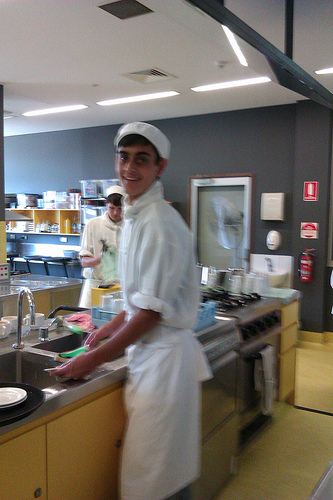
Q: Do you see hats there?
A: Yes, there is a hat.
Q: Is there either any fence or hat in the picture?
A: Yes, there is a hat.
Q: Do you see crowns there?
A: No, there are no crowns.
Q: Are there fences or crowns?
A: No, there are no crowns or fences.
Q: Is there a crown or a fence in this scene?
A: No, there are no crowns or fences.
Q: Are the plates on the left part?
A: Yes, the plates are on the left of the image.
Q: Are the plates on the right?
A: No, the plates are on the left of the image.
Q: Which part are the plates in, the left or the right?
A: The plates are on the left of the image.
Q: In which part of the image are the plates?
A: The plates are on the left of the image.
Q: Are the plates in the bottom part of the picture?
A: Yes, the plates are in the bottom of the image.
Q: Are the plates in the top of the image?
A: No, the plates are in the bottom of the image.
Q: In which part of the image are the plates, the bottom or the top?
A: The plates are in the bottom of the image.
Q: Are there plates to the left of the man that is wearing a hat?
A: Yes, there are plates to the left of the man.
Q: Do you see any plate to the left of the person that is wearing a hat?
A: Yes, there are plates to the left of the man.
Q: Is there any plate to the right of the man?
A: No, the plates are to the left of the man.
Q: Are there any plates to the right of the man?
A: No, the plates are to the left of the man.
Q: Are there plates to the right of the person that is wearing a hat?
A: No, the plates are to the left of the man.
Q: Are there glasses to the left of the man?
A: No, there are plates to the left of the man.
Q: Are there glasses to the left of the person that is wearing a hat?
A: No, there are plates to the left of the man.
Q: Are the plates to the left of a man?
A: Yes, the plates are to the left of a man.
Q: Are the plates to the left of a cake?
A: No, the plates are to the left of a man.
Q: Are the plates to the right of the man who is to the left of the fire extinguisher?
A: No, the plates are to the left of the man.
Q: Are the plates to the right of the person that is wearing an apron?
A: No, the plates are to the left of the man.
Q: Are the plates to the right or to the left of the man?
A: The plates are to the left of the man.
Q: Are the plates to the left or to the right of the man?
A: The plates are to the left of the man.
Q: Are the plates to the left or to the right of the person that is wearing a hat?
A: The plates are to the left of the man.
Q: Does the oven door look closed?
A: Yes, the oven door is closed.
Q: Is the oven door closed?
A: Yes, the oven door is closed.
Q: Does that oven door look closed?
A: Yes, the oven door is closed.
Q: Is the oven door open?
A: No, the oven door is closed.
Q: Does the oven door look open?
A: No, the oven door is closed.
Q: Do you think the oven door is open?
A: No, the oven door is closed.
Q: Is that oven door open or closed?
A: The oven door is closed.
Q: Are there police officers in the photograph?
A: No, there are no police officers.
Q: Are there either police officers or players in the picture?
A: No, there are no police officers or players.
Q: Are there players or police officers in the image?
A: No, there are no police officers or players.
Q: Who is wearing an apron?
A: The man is wearing an apron.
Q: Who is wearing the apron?
A: The man is wearing an apron.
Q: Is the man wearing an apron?
A: Yes, the man is wearing an apron.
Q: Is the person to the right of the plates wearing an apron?
A: Yes, the man is wearing an apron.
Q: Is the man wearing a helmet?
A: No, the man is wearing an apron.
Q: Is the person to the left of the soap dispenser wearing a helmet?
A: No, the man is wearing an apron.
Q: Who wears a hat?
A: The man wears a hat.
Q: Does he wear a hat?
A: Yes, the man wears a hat.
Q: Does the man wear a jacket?
A: No, the man wears a hat.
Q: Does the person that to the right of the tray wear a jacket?
A: No, the man wears a hat.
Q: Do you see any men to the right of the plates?
A: Yes, there is a man to the right of the plates.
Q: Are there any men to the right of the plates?
A: Yes, there is a man to the right of the plates.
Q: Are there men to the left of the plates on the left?
A: No, the man is to the right of the plates.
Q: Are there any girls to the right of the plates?
A: No, there is a man to the right of the plates.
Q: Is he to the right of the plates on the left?
A: Yes, the man is to the right of the plates.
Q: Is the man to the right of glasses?
A: No, the man is to the right of the plates.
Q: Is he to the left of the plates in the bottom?
A: No, the man is to the right of the plates.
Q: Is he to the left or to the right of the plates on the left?
A: The man is to the right of the plates.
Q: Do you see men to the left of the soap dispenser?
A: Yes, there is a man to the left of the soap dispenser.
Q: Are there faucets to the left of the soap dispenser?
A: No, there is a man to the left of the soap dispenser.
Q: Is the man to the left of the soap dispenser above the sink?
A: Yes, the man is to the left of the soap dispenser.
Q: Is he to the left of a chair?
A: No, the man is to the left of the soap dispenser.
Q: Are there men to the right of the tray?
A: Yes, there is a man to the right of the tray.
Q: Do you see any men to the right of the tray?
A: Yes, there is a man to the right of the tray.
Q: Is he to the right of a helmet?
A: No, the man is to the right of the tray.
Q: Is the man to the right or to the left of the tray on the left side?
A: The man is to the right of the tray.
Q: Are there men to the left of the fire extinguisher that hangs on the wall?
A: Yes, there is a man to the left of the fire extinguisher.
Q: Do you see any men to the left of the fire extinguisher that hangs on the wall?
A: Yes, there is a man to the left of the fire extinguisher.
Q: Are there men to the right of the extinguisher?
A: No, the man is to the left of the extinguisher.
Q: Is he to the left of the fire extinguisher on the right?
A: Yes, the man is to the left of the extinguisher.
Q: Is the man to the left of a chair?
A: No, the man is to the left of the extinguisher.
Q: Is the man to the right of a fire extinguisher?
A: No, the man is to the left of a fire extinguisher.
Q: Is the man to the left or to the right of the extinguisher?
A: The man is to the left of the extinguisher.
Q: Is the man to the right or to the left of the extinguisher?
A: The man is to the left of the extinguisher.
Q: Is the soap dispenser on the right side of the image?
A: Yes, the soap dispenser is on the right of the image.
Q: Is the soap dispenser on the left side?
A: No, the soap dispenser is on the right of the image.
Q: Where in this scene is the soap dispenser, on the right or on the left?
A: The soap dispenser is on the right of the image.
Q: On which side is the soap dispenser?
A: The soap dispenser is on the right of the image.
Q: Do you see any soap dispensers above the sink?
A: Yes, there is a soap dispenser above the sink.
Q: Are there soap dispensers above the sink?
A: Yes, there is a soap dispenser above the sink.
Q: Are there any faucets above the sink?
A: No, there is a soap dispenser above the sink.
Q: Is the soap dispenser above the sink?
A: Yes, the soap dispenser is above the sink.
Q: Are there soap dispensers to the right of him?
A: Yes, there is a soap dispenser to the right of the man.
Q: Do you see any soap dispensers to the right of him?
A: Yes, there is a soap dispenser to the right of the man.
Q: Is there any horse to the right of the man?
A: No, there is a soap dispenser to the right of the man.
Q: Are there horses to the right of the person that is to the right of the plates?
A: No, there is a soap dispenser to the right of the man.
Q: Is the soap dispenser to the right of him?
A: Yes, the soap dispenser is to the right of the man.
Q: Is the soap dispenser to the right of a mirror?
A: No, the soap dispenser is to the right of the man.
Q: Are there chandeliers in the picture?
A: No, there are no chandeliers.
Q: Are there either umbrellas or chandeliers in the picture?
A: No, there are no chandeliers or umbrellas.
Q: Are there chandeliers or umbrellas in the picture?
A: No, there are no chandeliers or umbrellas.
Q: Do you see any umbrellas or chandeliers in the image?
A: No, there are no chandeliers or umbrellas.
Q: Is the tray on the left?
A: Yes, the tray is on the left of the image.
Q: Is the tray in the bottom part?
A: Yes, the tray is in the bottom of the image.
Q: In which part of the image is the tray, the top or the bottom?
A: The tray is in the bottom of the image.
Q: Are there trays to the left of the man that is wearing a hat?
A: Yes, there is a tray to the left of the man.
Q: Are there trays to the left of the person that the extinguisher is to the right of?
A: Yes, there is a tray to the left of the man.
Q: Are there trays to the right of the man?
A: No, the tray is to the left of the man.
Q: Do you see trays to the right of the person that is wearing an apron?
A: No, the tray is to the left of the man.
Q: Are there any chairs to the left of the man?
A: No, there is a tray to the left of the man.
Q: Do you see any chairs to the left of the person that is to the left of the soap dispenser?
A: No, there is a tray to the left of the man.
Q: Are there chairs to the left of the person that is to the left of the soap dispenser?
A: No, there is a tray to the left of the man.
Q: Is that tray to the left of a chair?
A: No, the tray is to the left of the man.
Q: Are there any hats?
A: Yes, there is a hat.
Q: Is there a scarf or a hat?
A: Yes, there is a hat.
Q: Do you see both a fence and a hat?
A: No, there is a hat but no fences.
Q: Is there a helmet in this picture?
A: No, there are no helmets.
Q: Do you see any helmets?
A: No, there are no helmets.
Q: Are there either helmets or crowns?
A: No, there are no helmets or crowns.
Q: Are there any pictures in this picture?
A: No, there are no pictures.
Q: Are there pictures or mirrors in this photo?
A: No, there are no pictures or mirrors.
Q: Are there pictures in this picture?
A: No, there are no pictures.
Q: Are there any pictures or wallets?
A: No, there are no pictures or wallets.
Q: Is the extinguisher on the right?
A: Yes, the extinguisher is on the right of the image.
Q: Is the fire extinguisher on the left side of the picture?
A: No, the fire extinguisher is on the right of the image.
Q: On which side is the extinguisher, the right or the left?
A: The extinguisher is on the right of the image.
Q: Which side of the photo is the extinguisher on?
A: The extinguisher is on the right of the image.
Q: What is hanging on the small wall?
A: The extinguisher is hanging on the wall.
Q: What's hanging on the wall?
A: The extinguisher is hanging on the wall.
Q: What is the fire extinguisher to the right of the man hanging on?
A: The extinguisher is hanging on the wall.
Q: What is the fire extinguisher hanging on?
A: The extinguisher is hanging on the wall.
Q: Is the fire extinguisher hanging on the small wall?
A: Yes, the fire extinguisher is hanging on the wall.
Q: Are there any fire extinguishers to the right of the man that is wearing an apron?
A: Yes, there is a fire extinguisher to the right of the man.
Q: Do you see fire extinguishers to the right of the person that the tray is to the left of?
A: Yes, there is a fire extinguisher to the right of the man.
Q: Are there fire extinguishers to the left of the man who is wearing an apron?
A: No, the fire extinguisher is to the right of the man.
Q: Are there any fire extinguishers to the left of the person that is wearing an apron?
A: No, the fire extinguisher is to the right of the man.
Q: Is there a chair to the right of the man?
A: No, there is a fire extinguisher to the right of the man.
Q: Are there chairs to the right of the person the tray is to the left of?
A: No, there is a fire extinguisher to the right of the man.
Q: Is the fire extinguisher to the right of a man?
A: Yes, the fire extinguisher is to the right of a man.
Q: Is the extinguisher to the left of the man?
A: No, the extinguisher is to the right of the man.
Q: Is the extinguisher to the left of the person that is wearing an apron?
A: No, the extinguisher is to the right of the man.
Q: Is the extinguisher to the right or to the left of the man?
A: The extinguisher is to the right of the man.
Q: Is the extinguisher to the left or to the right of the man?
A: The extinguisher is to the right of the man.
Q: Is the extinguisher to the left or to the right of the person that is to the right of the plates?
A: The extinguisher is to the right of the man.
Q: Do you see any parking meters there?
A: No, there are no parking meters.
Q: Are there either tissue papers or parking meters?
A: No, there are no parking meters or tissue papers.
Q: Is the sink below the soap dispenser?
A: Yes, the sink is below the soap dispenser.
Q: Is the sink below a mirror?
A: No, the sink is below the soap dispenser.